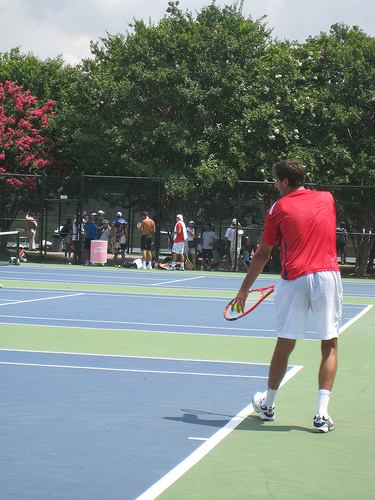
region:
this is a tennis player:
[205, 160, 361, 442]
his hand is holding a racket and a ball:
[214, 251, 287, 321]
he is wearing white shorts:
[275, 280, 341, 338]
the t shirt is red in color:
[282, 201, 327, 272]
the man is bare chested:
[142, 220, 151, 232]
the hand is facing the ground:
[224, 245, 271, 320]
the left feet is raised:
[248, 391, 271, 418]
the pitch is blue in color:
[46, 402, 165, 464]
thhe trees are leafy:
[14, 62, 370, 155]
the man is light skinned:
[323, 362, 335, 371]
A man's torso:
[256, 153, 352, 280]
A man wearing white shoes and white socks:
[238, 384, 348, 439]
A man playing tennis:
[216, 149, 352, 438]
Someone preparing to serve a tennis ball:
[218, 281, 277, 331]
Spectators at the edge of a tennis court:
[50, 202, 247, 272]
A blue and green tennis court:
[0, 267, 222, 498]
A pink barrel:
[87, 237, 113, 268]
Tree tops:
[70, 0, 373, 162]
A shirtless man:
[135, 211, 161, 273]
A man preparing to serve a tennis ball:
[211, 154, 357, 439]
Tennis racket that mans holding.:
[225, 282, 283, 321]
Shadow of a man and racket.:
[162, 402, 319, 433]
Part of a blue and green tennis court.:
[1, 228, 373, 301]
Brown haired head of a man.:
[270, 161, 312, 191]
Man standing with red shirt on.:
[172, 211, 185, 269]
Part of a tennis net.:
[1, 227, 20, 262]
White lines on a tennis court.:
[187, 435, 222, 448]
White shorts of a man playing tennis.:
[275, 266, 340, 341]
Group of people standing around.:
[61, 210, 133, 265]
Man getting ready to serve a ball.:
[229, 158, 345, 435]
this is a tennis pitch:
[30, 273, 183, 375]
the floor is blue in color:
[50, 376, 130, 468]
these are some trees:
[101, 24, 345, 148]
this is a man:
[230, 154, 346, 433]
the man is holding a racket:
[220, 263, 273, 325]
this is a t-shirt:
[285, 207, 325, 261]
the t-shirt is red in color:
[291, 216, 325, 257]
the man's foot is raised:
[250, 391, 273, 423]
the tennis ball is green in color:
[234, 300, 244, 311]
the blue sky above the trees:
[2, 3, 372, 35]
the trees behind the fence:
[5, 15, 372, 183]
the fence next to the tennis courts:
[5, 175, 373, 280]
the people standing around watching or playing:
[26, 205, 348, 280]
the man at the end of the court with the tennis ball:
[218, 159, 340, 435]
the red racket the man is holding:
[223, 274, 270, 321]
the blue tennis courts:
[0, 264, 367, 496]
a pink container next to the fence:
[87, 234, 110, 265]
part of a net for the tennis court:
[2, 229, 21, 259]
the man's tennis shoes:
[249, 389, 343, 440]